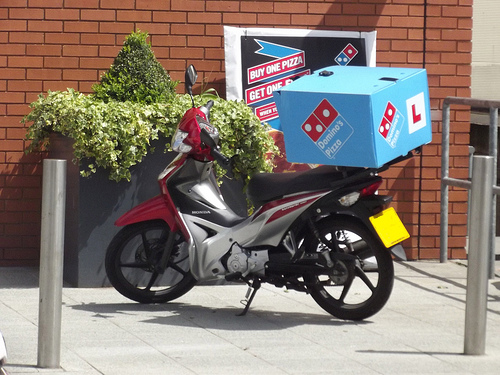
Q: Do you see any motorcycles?
A: Yes, there is a motorcycle.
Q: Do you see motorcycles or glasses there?
A: Yes, there is a motorcycle.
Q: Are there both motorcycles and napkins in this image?
A: No, there is a motorcycle but no napkins.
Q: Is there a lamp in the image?
A: No, there are no lamps.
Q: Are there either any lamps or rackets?
A: No, there are no lamps or rackets.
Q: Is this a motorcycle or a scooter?
A: This is a motorcycle.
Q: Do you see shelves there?
A: No, there are no shelves.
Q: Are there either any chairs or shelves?
A: No, there are no shelves or chairs.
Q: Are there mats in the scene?
A: No, there are no mats.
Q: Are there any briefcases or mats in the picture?
A: No, there are no mats or briefcases.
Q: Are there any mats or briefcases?
A: No, there are no mats or briefcases.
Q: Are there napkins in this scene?
A: No, there are no napkins.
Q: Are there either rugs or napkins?
A: No, there are no napkins or rugs.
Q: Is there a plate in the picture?
A: Yes, there is a plate.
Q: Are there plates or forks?
A: Yes, there is a plate.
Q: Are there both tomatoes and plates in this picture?
A: No, there is a plate but no tomatoes.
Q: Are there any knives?
A: No, there are no knives.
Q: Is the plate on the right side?
A: Yes, the plate is on the right of the image.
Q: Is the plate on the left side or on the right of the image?
A: The plate is on the right of the image.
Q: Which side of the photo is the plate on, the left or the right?
A: The plate is on the right of the image.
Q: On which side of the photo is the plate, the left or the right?
A: The plate is on the right of the image.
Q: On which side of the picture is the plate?
A: The plate is on the right of the image.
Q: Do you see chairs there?
A: No, there are no chairs.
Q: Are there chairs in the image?
A: No, there are no chairs.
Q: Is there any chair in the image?
A: No, there are no chairs.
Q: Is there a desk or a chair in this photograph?
A: No, there are no chairs or desks.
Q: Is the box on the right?
A: Yes, the box is on the right of the image.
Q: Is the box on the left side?
A: No, the box is on the right of the image.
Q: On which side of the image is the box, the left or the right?
A: The box is on the right of the image.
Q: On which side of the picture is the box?
A: The box is on the right of the image.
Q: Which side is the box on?
A: The box is on the right of the image.